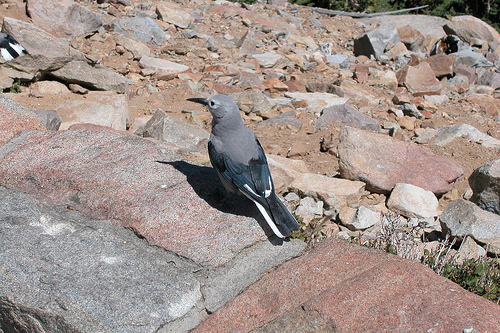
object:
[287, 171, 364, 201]
rock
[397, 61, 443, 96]
rock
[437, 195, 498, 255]
rock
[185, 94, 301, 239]
bird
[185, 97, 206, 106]
beak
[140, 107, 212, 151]
rock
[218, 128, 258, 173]
back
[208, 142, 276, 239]
blue feathers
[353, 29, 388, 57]
rock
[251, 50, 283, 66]
rock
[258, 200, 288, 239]
tail feather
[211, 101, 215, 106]
eye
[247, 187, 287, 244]
white feathers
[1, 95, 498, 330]
wall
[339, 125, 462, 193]
lock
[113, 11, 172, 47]
rock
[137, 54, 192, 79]
rock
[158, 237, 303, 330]
grout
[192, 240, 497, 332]
brick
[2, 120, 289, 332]
rock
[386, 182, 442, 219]
brick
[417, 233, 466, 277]
grass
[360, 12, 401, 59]
rock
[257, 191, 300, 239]
tail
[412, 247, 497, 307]
plants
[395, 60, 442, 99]
rock/ground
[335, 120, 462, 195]
rock/ground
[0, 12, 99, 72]
rock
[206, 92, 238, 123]
head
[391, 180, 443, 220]
rock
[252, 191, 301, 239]
bird's feathers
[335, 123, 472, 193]
rock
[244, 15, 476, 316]
ground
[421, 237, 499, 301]
bush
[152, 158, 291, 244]
shadow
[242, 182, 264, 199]
stripe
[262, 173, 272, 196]
stripe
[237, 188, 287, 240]
stripe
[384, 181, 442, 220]
rock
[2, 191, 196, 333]
brick